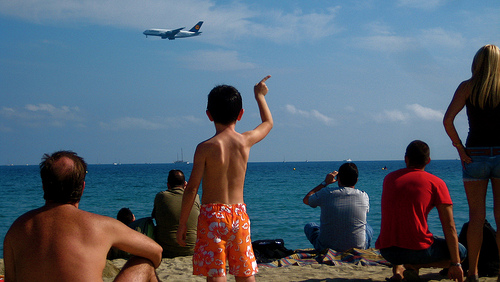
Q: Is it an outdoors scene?
A: Yes, it is outdoors.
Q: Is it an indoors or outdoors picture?
A: It is outdoors.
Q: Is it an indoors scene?
A: No, it is outdoors.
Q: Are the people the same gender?
A: No, they are both male and female.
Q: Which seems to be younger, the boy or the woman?
A: The boy is younger than the woman.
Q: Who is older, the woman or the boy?
A: The woman is older than the boy.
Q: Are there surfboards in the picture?
A: No, there are no surfboards.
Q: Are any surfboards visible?
A: No, there are no surfboards.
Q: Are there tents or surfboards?
A: No, there are no surfboards or tents.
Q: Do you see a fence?
A: No, there are no fences.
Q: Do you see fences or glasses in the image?
A: No, there are no fences or glasses.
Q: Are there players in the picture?
A: No, there are no players.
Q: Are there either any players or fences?
A: No, there are no players or fences.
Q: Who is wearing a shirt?
A: The man is wearing a shirt.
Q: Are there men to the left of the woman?
A: Yes, there is a man to the left of the woman.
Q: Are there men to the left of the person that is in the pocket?
A: Yes, there is a man to the left of the woman.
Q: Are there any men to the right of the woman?
A: No, the man is to the left of the woman.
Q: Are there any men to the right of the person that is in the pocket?
A: No, the man is to the left of the woman.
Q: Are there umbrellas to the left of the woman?
A: No, there is a man to the left of the woman.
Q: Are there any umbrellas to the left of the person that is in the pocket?
A: No, there is a man to the left of the woman.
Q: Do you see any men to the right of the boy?
A: Yes, there is a man to the right of the boy.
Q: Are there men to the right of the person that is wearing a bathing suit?
A: Yes, there is a man to the right of the boy.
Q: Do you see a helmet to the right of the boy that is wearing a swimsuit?
A: No, there is a man to the right of the boy.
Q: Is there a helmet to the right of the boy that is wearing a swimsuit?
A: No, there is a man to the right of the boy.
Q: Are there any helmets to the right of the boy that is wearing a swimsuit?
A: No, there is a man to the right of the boy.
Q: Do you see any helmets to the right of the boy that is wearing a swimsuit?
A: No, there is a man to the right of the boy.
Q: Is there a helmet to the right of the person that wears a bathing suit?
A: No, there is a man to the right of the boy.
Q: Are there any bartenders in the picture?
A: No, there are no bartenders.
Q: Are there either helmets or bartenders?
A: No, there are no bartenders or helmets.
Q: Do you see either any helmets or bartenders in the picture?
A: No, there are no bartenders or helmets.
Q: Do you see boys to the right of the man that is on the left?
A: Yes, there is a boy to the right of the man.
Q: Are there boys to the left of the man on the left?
A: No, the boy is to the right of the man.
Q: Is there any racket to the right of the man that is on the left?
A: No, there is a boy to the right of the man.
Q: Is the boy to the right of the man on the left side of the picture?
A: Yes, the boy is to the right of the man.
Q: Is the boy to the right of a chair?
A: No, the boy is to the right of the man.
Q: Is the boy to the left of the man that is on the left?
A: No, the boy is to the right of the man.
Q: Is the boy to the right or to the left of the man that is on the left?
A: The boy is to the right of the man.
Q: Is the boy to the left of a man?
A: No, the boy is to the right of a man.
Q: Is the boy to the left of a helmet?
A: No, the boy is to the left of a man.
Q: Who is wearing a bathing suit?
A: The boy is wearing a bathing suit.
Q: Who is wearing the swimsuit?
A: The boy is wearing a bathing suit.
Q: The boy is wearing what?
A: The boy is wearing a bathing suit.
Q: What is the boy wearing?
A: The boy is wearing a bathing suit.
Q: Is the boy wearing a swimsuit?
A: Yes, the boy is wearing a swimsuit.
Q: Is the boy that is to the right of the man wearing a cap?
A: No, the boy is wearing a swimsuit.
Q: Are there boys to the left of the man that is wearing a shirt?
A: Yes, there is a boy to the left of the man.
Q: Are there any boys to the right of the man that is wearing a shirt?
A: No, the boy is to the left of the man.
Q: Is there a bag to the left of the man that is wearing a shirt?
A: No, there is a boy to the left of the man.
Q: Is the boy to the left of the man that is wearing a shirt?
A: Yes, the boy is to the left of the man.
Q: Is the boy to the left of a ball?
A: No, the boy is to the left of the man.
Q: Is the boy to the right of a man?
A: No, the boy is to the left of a man.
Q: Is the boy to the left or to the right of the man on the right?
A: The boy is to the left of the man.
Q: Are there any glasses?
A: No, there are no glasses.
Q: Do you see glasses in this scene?
A: No, there are no glasses.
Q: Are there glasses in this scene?
A: No, there are no glasses.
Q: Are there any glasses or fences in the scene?
A: No, there are no glasses or fences.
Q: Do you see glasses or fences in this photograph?
A: No, there are no glasses or fences.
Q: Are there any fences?
A: No, there are no fences.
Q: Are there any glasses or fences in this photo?
A: No, there are no fences or glasses.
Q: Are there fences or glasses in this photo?
A: No, there are no fences or glasses.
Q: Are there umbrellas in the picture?
A: No, there are no umbrellas.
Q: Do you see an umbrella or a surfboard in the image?
A: No, there are no umbrellas or surfboards.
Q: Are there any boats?
A: Yes, there is a boat.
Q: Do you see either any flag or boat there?
A: Yes, there is a boat.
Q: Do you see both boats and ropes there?
A: No, there is a boat but no ropes.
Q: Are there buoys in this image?
A: No, there are no buoys.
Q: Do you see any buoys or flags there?
A: No, there are no buoys or flags.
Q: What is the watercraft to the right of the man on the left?
A: The watercraft is a boat.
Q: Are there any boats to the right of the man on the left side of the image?
A: Yes, there is a boat to the right of the man.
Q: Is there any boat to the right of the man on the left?
A: Yes, there is a boat to the right of the man.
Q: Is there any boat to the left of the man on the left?
A: No, the boat is to the right of the man.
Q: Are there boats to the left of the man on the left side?
A: No, the boat is to the right of the man.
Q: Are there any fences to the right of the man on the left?
A: No, there is a boat to the right of the man.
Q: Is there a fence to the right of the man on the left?
A: No, there is a boat to the right of the man.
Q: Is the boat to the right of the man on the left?
A: Yes, the boat is to the right of the man.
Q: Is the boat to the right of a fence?
A: No, the boat is to the right of the man.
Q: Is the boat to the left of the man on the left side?
A: No, the boat is to the right of the man.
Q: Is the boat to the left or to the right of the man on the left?
A: The boat is to the right of the man.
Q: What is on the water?
A: The boat is on the water.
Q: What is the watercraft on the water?
A: The watercraft is a boat.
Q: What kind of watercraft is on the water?
A: The watercraft is a boat.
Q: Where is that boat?
A: The boat is on the water.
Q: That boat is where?
A: The boat is on the water.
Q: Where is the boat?
A: The boat is on the water.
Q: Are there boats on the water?
A: Yes, there is a boat on the water.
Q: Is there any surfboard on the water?
A: No, there is a boat on the water.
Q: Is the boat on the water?
A: Yes, the boat is on the water.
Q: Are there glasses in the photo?
A: No, there are no glasses.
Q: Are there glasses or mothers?
A: No, there are no glasses or mothers.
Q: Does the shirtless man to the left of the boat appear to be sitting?
A: Yes, the man is sitting.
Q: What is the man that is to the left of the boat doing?
A: The man is sitting.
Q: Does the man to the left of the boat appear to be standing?
A: No, the man is sitting.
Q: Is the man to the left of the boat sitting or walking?
A: The man is sitting.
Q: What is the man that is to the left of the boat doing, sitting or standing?
A: The man is sitting.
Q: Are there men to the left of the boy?
A: Yes, there is a man to the left of the boy.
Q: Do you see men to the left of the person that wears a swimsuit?
A: Yes, there is a man to the left of the boy.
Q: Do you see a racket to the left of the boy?
A: No, there is a man to the left of the boy.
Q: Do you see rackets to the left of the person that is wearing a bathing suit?
A: No, there is a man to the left of the boy.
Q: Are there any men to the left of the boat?
A: Yes, there is a man to the left of the boat.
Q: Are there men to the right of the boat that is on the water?
A: No, the man is to the left of the boat.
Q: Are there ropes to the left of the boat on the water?
A: No, there is a man to the left of the boat.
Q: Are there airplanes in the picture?
A: Yes, there is an airplane.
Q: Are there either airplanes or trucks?
A: Yes, there is an airplane.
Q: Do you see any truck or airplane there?
A: Yes, there is an airplane.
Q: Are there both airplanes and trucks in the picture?
A: No, there is an airplane but no trucks.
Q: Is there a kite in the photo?
A: No, there are no kites.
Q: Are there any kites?
A: No, there are no kites.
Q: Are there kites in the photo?
A: No, there are no kites.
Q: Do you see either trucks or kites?
A: No, there are no kites or trucks.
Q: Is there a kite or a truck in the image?
A: No, there are no kites or trucks.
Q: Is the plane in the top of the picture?
A: Yes, the plane is in the top of the image.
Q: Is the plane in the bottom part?
A: No, the plane is in the top of the image.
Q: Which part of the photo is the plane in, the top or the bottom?
A: The plane is in the top of the image.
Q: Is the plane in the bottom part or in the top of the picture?
A: The plane is in the top of the image.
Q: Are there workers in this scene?
A: No, there are no workers.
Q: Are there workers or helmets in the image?
A: No, there are no workers or helmets.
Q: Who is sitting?
A: The man is sitting.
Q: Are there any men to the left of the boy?
A: Yes, there is a man to the left of the boy.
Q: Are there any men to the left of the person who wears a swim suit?
A: Yes, there is a man to the left of the boy.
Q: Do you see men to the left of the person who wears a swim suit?
A: Yes, there is a man to the left of the boy.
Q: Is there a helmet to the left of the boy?
A: No, there is a man to the left of the boy.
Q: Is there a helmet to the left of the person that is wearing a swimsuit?
A: No, there is a man to the left of the boy.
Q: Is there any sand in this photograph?
A: Yes, there is sand.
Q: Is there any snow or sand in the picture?
A: Yes, there is sand.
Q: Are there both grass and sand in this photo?
A: No, there is sand but no grass.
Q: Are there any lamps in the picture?
A: No, there are no lamps.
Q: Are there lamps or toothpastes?
A: No, there are no lamps or toothpastes.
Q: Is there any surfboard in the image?
A: No, there are no surfboards.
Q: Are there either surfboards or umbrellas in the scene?
A: No, there are no surfboards or umbrellas.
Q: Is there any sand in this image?
A: Yes, there is sand.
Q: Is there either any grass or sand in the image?
A: Yes, there is sand.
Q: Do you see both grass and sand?
A: No, there is sand but no grass.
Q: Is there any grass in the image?
A: No, there is no grass.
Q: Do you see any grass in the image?
A: No, there is no grass.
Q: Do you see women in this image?
A: Yes, there is a woman.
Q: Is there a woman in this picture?
A: Yes, there is a woman.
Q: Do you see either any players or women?
A: Yes, there is a woman.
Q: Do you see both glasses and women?
A: No, there is a woman but no glasses.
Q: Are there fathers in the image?
A: No, there are no fathers.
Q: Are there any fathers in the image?
A: No, there are no fathers.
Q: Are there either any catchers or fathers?
A: No, there are no fathers or catchers.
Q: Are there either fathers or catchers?
A: No, there are no fathers or catchers.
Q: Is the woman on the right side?
A: Yes, the woman is on the right of the image.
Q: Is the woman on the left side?
A: No, the woman is on the right of the image.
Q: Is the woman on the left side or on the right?
A: The woman is on the right of the image.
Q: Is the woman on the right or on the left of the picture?
A: The woman is on the right of the image.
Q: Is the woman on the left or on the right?
A: The woman is on the right of the image.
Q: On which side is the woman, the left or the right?
A: The woman is on the right of the image.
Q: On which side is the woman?
A: The woman is on the right of the image.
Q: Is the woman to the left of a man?
A: No, the woman is to the right of a man.